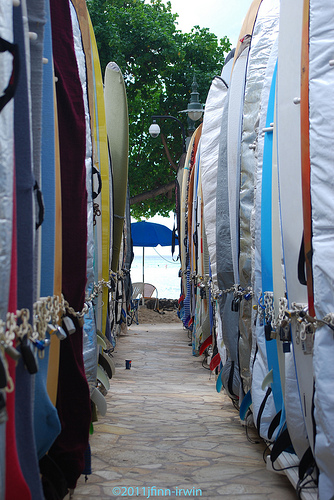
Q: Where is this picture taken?
A: At a surfboard rental or sales place.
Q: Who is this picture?
A: Not one person.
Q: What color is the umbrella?
A: Blue.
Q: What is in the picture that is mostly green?
A: A tree.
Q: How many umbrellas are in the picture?
A: One.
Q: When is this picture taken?
A: During the day.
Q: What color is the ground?
A: White and beige.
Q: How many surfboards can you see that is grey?
A: One.